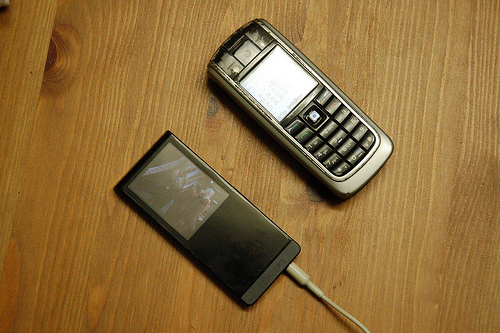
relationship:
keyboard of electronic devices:
[283, 87, 379, 179] [206, 18, 396, 198]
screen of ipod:
[126, 136, 232, 240] [90, 122, 305, 309]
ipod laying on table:
[90, 122, 305, 309] [3, 2, 498, 332]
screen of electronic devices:
[237, 41, 320, 122] [206, 18, 396, 198]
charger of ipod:
[285, 259, 371, 333] [90, 122, 305, 309]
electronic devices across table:
[86, 14, 397, 308] [3, 2, 498, 332]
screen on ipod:
[126, 136, 232, 240] [110, 131, 300, 311]